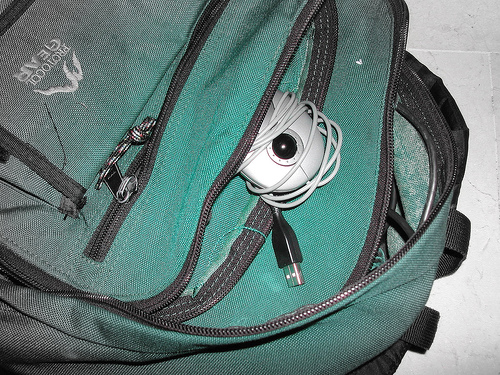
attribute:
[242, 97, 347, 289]
mouse — grey, white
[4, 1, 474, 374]
backpack — aqua, worn, green, open, unzipped, black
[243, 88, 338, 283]
cord — white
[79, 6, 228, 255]
zipper — black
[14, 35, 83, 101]
emblem — white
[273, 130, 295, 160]
ball — black, built-in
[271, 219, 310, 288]
usb connector — black, silver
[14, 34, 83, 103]
logo — white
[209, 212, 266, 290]
stitching — frayed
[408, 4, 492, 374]
ground — tiled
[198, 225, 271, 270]
string — green